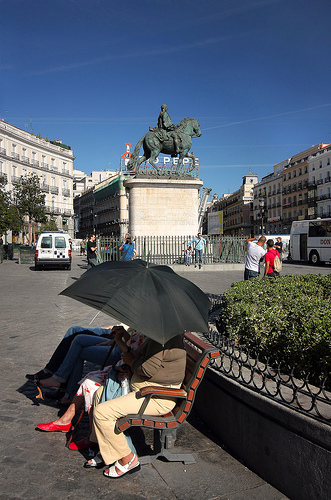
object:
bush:
[220, 274, 331, 362]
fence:
[202, 291, 330, 425]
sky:
[0, 0, 331, 188]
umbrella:
[57, 251, 213, 348]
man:
[187, 232, 206, 269]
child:
[181, 245, 194, 266]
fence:
[93, 233, 248, 263]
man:
[264, 239, 282, 277]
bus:
[290, 216, 331, 265]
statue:
[127, 103, 202, 176]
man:
[157, 104, 184, 153]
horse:
[126, 117, 202, 174]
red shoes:
[37, 417, 89, 451]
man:
[244, 235, 267, 281]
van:
[35, 230, 72, 269]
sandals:
[104, 447, 142, 479]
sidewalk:
[0, 253, 331, 499]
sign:
[208, 210, 224, 236]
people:
[25, 321, 187, 479]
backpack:
[269, 250, 282, 273]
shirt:
[265, 248, 280, 273]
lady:
[37, 328, 150, 451]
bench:
[115, 330, 220, 466]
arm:
[135, 385, 187, 415]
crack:
[234, 479, 256, 492]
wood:
[186, 343, 219, 409]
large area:
[0, 0, 331, 194]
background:
[0, 0, 331, 281]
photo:
[94, 322, 134, 359]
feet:
[37, 421, 72, 434]